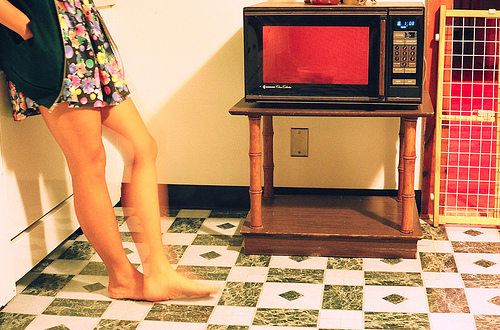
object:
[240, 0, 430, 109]
microwave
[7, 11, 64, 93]
pocket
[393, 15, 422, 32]
display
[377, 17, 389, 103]
handle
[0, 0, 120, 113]
floral skirt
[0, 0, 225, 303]
woman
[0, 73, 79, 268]
shadow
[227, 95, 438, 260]
stand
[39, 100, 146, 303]
leg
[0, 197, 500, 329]
floor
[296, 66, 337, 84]
food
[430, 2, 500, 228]
baby gate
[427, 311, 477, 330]
floor tiles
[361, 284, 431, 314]
tile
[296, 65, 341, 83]
dish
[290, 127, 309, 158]
socket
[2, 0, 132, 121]
dress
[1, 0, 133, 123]
clothing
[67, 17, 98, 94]
pattern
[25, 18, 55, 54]
hand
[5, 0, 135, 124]
floral pattern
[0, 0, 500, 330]
kitchen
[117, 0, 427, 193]
wall